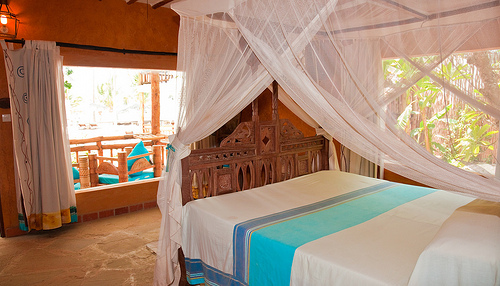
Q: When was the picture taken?
A: Daytime.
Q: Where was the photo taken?
A: In a bedroom.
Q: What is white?
A: Curtains.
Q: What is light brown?
A: Floor.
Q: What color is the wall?
A: Brown.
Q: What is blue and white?
A: Bed sheets.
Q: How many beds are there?
A: One.